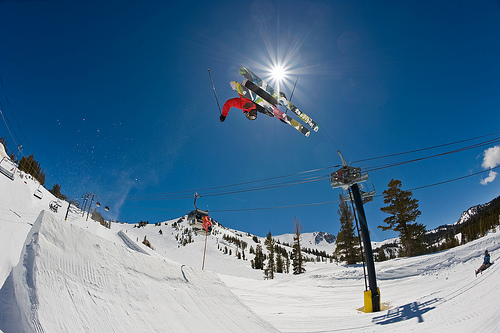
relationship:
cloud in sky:
[474, 144, 500, 186] [0, 0, 499, 241]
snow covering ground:
[68, 259, 256, 323] [13, 225, 461, 330]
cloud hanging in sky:
[60, 96, 175, 214] [0, 0, 499, 241]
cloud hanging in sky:
[474, 144, 500, 186] [0, 0, 499, 241]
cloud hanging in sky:
[60, 96, 175, 214] [12, 5, 498, 226]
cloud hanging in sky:
[482, 141, 498, 186] [12, 5, 498, 226]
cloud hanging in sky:
[56, 157, 156, 224] [12, 5, 498, 226]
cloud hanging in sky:
[474, 144, 500, 186] [12, 5, 498, 226]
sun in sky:
[251, 50, 312, 105] [3, 1, 499, 275]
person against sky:
[217, 79, 287, 124] [0, 0, 499, 241]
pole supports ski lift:
[336, 156, 386, 313] [40, 128, 497, 215]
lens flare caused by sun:
[198, 48, 309, 113] [272, 60, 287, 81]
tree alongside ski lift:
[332, 192, 365, 266] [179, 189, 219, 241]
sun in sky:
[260, 60, 296, 85] [0, 0, 499, 241]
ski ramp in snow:
[1, 207, 281, 331] [0, 203, 497, 331]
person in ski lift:
[196, 206, 217, 238] [0, 139, 498, 254]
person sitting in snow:
[473, 248, 494, 275] [0, 142, 498, 329]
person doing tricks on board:
[206, 77, 258, 130] [179, 47, 312, 152]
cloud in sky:
[474, 144, 500, 186] [2, 17, 489, 222]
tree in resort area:
[376, 177, 427, 255] [6, 148, 499, 327]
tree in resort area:
[254, 243, 266, 268] [6, 148, 499, 327]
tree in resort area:
[333, 192, 365, 264] [6, 148, 499, 327]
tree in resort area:
[263, 240, 275, 277] [6, 148, 499, 327]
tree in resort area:
[292, 215, 306, 273] [6, 148, 499, 327]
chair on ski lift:
[183, 202, 214, 235] [9, 142, 498, 209]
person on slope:
[479, 243, 491, 266] [305, 228, 496, 330]